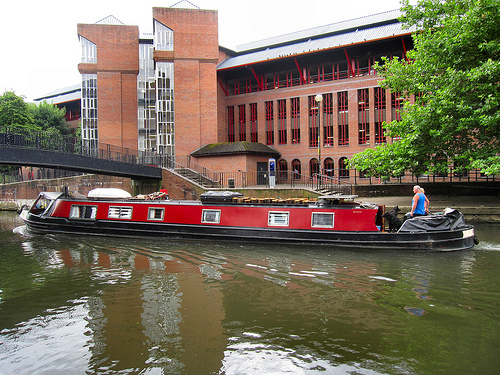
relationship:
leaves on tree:
[337, 142, 421, 177] [338, 2, 497, 185]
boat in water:
[15, 187, 479, 254] [0, 210, 499, 373]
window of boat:
[268, 210, 294, 228] [21, 182, 481, 249]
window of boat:
[149, 205, 166, 222] [28, 187, 491, 254]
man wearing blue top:
[408, 184, 430, 227] [408, 192, 427, 217]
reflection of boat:
[24, 235, 399, 372] [15, 187, 479, 254]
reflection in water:
[24, 235, 399, 372] [0, 210, 499, 373]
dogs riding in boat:
[363, 154, 420, 235] [58, 177, 483, 295]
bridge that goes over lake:
[2, 127, 175, 183] [5, 225, 499, 372]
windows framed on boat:
[114, 86, 365, 304] [131, 170, 355, 244]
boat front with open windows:
[15, 187, 479, 254] [25, 191, 53, 218]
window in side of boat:
[310, 210, 334, 227] [78, 158, 168, 256]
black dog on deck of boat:
[382, 205, 405, 230] [52, 201, 379, 235]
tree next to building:
[338, 2, 497, 185] [21, 2, 498, 169]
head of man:
[410, 180, 425, 196] [403, 185, 430, 222]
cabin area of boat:
[17, 173, 70, 236] [21, 182, 481, 249]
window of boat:
[201, 209, 221, 224] [21, 182, 481, 249]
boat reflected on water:
[28, 187, 491, 254] [0, 210, 499, 373]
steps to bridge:
[163, 165, 213, 191] [2, 127, 175, 183]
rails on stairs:
[158, 159, 204, 189] [163, 162, 223, 185]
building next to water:
[28, 0, 499, 188] [0, 210, 499, 373]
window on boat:
[198, 209, 222, 222] [10, 174, 478, 272]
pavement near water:
[367, 182, 497, 214] [0, 210, 499, 373]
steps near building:
[300, 173, 352, 201] [28, 0, 499, 188]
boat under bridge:
[28, 187, 491, 254] [2, 127, 226, 197]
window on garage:
[337, 89, 349, 149] [190, 4, 480, 191]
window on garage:
[235, 99, 244, 142] [33, 0, 497, 196]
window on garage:
[264, 99, 275, 145] [33, 0, 497, 196]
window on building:
[246, 101, 260, 146] [28, 0, 499, 188]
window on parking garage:
[258, 96, 276, 148] [40, 0, 484, 196]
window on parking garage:
[320, 89, 335, 151] [22, 0, 469, 176]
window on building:
[320, 89, 335, 151] [28, 0, 499, 188]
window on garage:
[337, 89, 350, 147] [33, 0, 497, 196]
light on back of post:
[309, 90, 326, 105] [309, 98, 328, 192]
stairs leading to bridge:
[135, 129, 240, 210] [0, 107, 169, 183]